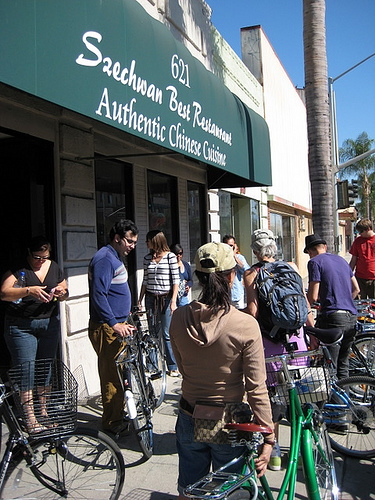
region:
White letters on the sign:
[61, 14, 281, 179]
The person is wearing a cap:
[188, 242, 246, 291]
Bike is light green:
[157, 331, 364, 498]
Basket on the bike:
[2, 358, 96, 446]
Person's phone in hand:
[42, 284, 75, 312]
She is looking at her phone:
[9, 239, 84, 362]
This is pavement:
[133, 461, 168, 483]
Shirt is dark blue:
[299, 253, 364, 321]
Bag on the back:
[187, 392, 258, 452]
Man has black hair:
[97, 217, 143, 257]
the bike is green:
[225, 333, 332, 495]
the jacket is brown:
[144, 262, 294, 476]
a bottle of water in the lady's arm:
[3, 264, 29, 305]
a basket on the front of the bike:
[0, 351, 84, 446]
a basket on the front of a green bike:
[250, 344, 335, 408]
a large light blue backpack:
[254, 254, 310, 340]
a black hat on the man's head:
[300, 228, 329, 257]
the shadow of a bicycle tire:
[52, 409, 158, 472]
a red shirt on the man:
[347, 228, 373, 285]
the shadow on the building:
[158, 0, 233, 90]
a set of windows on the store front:
[134, 150, 212, 270]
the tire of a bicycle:
[0, 422, 129, 498]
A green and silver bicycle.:
[184, 339, 339, 498]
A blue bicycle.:
[303, 326, 374, 459]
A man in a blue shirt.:
[87, 216, 142, 437]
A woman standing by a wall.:
[0, 239, 69, 435]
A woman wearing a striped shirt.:
[137, 228, 180, 376]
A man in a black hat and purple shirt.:
[304, 231, 359, 379]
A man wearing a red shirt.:
[348, 218, 374, 299]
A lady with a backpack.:
[235, 227, 319, 470]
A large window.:
[267, 207, 299, 268]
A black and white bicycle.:
[113, 303, 169, 456]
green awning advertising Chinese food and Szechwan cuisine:
[4, 0, 277, 186]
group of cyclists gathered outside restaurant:
[8, 215, 373, 496]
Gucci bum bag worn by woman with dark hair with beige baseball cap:
[189, 399, 229, 448]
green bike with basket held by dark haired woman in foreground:
[180, 341, 342, 495]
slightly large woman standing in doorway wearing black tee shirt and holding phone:
[4, 238, 71, 438]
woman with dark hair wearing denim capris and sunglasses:
[2, 237, 71, 425]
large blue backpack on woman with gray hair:
[253, 261, 304, 352]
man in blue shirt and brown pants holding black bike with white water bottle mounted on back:
[85, 215, 169, 462]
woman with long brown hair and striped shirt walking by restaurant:
[135, 228, 182, 374]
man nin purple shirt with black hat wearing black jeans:
[297, 228, 363, 432]